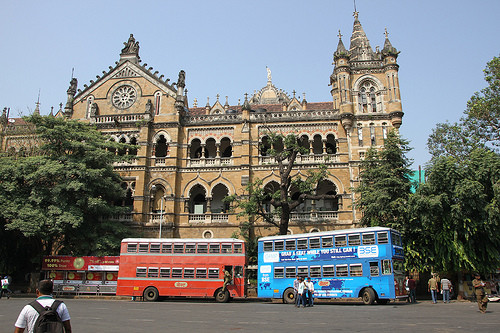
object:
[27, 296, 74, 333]
backpack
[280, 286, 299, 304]
wheel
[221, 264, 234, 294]
door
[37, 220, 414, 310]
buses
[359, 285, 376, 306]
tire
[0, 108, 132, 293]
tree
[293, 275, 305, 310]
people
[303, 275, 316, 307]
people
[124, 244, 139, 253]
window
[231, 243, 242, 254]
window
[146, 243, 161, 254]
window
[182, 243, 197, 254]
window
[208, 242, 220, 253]
window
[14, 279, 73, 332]
man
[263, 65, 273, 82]
statue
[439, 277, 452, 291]
gray shirt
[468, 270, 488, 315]
person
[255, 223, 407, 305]
bus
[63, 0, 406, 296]
building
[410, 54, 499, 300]
tree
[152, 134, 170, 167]
window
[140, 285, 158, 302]
wheels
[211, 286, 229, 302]
wheel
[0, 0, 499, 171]
sky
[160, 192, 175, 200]
lamp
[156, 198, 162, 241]
post